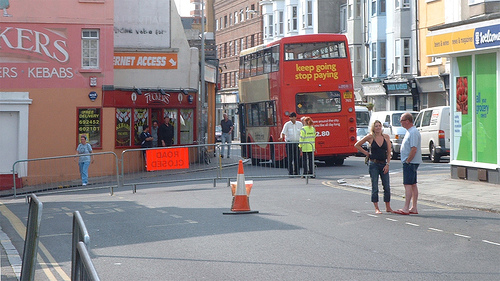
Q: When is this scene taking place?
A: Daytime.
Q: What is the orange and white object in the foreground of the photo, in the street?
A: Cone.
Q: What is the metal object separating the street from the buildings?
A: Fence.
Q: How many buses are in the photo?
A: One.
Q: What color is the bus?
A: Red.